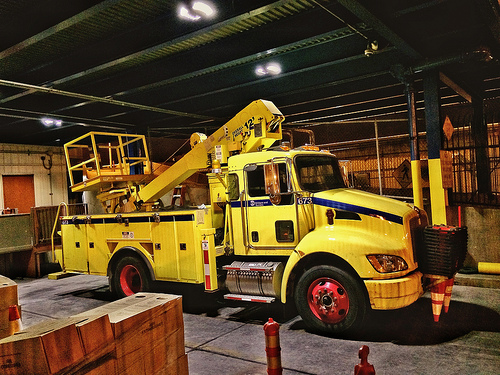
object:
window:
[248, 162, 290, 198]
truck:
[48, 97, 468, 339]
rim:
[314, 287, 347, 321]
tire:
[293, 263, 366, 335]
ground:
[17, 266, 500, 374]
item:
[223, 260, 282, 299]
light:
[177, 1, 223, 21]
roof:
[0, 0, 498, 129]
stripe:
[64, 214, 205, 227]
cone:
[429, 276, 444, 322]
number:
[299, 200, 318, 207]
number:
[243, 116, 254, 130]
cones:
[443, 278, 455, 313]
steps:
[210, 254, 286, 305]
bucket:
[69, 163, 137, 213]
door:
[4, 174, 37, 216]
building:
[0, 0, 500, 266]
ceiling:
[0, 0, 500, 139]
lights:
[280, 143, 338, 151]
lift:
[62, 97, 287, 212]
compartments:
[55, 213, 202, 286]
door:
[238, 163, 298, 250]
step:
[39, 227, 65, 275]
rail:
[50, 197, 68, 261]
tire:
[107, 250, 153, 307]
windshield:
[295, 155, 348, 191]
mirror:
[274, 157, 294, 201]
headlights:
[366, 252, 409, 273]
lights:
[252, 61, 287, 78]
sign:
[441, 114, 455, 139]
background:
[0, 0, 500, 190]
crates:
[0, 216, 190, 275]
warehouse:
[2, 2, 500, 375]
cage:
[58, 129, 153, 192]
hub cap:
[115, 262, 142, 295]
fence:
[31, 203, 92, 247]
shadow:
[286, 293, 500, 346]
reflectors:
[199, 246, 220, 295]